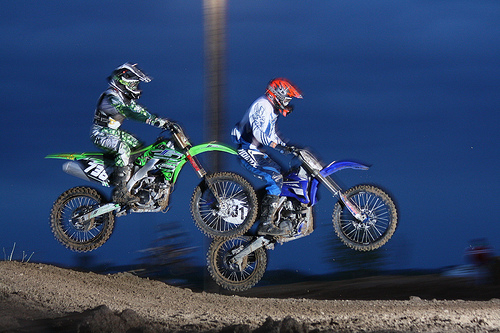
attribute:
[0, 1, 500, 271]
sky — blue, nighttime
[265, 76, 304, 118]
helmet — red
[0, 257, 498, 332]
ground — gravel, rough, brown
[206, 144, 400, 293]
motorbike — blue, racing, mid air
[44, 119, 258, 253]
motorbike — green, mid air, racing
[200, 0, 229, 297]
pole — metal, gray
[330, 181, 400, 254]
front wheel — black, mid air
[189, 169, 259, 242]
front wheel — blak, mid air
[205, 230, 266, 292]
back wheel — black, mid air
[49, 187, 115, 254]
back wheel — black, mid air